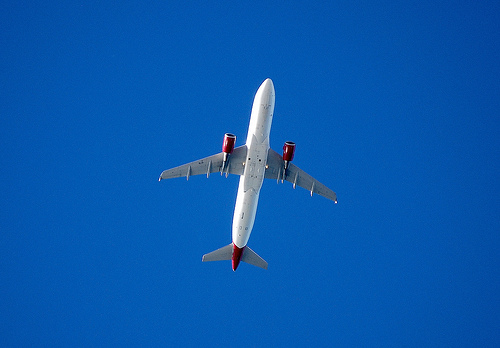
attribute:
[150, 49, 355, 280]
plane — white, red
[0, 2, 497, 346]
sky — blue, clear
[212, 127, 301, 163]
engines — red